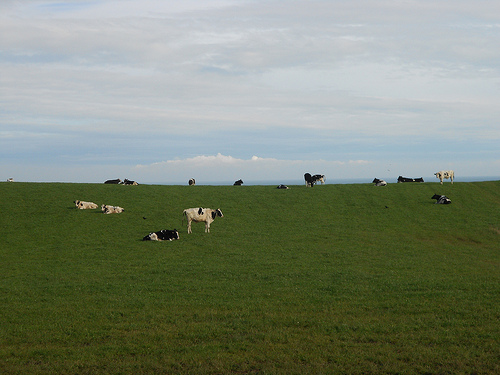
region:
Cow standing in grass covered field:
[178, 200, 225, 235]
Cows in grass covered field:
[70, 168, 471, 260]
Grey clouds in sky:
[9, 9, 498, 167]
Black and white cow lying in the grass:
[132, 225, 184, 247]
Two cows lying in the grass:
[63, 197, 133, 218]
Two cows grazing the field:
[297, 170, 332, 186]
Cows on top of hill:
[98, 165, 465, 191]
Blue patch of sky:
[16, 131, 406, 157]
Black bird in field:
[377, 200, 388, 210]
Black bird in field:
[137, 212, 154, 223]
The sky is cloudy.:
[3, 0, 488, 165]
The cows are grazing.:
[75, 166, 465, 244]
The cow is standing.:
[178, 201, 225, 231]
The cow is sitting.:
[137, 226, 185, 246]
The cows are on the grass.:
[60, 166, 477, 241]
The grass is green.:
[0, 180, 495, 365]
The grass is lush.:
[5, 178, 496, 363]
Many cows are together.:
[62, 160, 482, 257]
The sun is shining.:
[0, 0, 492, 365]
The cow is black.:
[133, 220, 188, 251]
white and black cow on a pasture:
[176, 202, 227, 239]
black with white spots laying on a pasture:
[140, 228, 183, 243]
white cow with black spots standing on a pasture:
[178, 205, 226, 235]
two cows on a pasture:
[139, 203, 227, 244]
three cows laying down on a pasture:
[70, 196, 182, 243]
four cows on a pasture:
[70, 196, 225, 243]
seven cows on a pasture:
[70, 175, 227, 242]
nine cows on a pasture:
[73, 177, 290, 243]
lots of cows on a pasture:
[70, 168, 472, 243]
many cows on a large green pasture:
[2, 168, 499, 373]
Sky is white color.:
[66, 23, 385, 116]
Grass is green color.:
[266, 210, 440, 331]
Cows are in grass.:
[61, 152, 491, 264]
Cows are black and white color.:
[73, 155, 475, 263]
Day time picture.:
[23, 30, 464, 340]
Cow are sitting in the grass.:
[71, 195, 186, 243]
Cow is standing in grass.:
[176, 188, 227, 241]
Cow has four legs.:
[185, 210, 243, 245]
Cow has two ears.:
[428, 169, 450, 186]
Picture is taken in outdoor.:
[13, 18, 491, 357]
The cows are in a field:
[26, 55, 476, 363]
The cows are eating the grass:
[30, 67, 492, 328]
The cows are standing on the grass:
[22, 72, 480, 332]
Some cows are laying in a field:
[11, 27, 484, 347]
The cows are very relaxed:
[22, 42, 485, 328]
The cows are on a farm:
[46, 55, 494, 336]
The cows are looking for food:
[25, 40, 491, 335]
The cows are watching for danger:
[31, 50, 481, 337]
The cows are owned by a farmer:
[32, 62, 492, 372]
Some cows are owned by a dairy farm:
[23, 36, 488, 321]